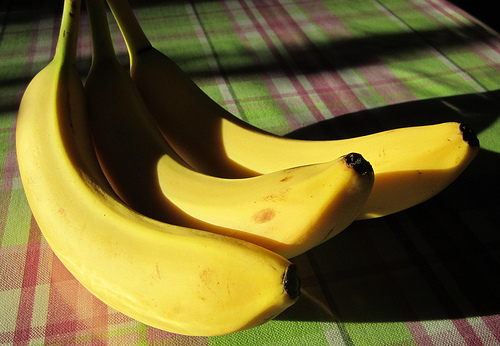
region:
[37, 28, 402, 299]
yellow bananas on table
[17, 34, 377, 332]
bananas are bunched together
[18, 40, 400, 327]
bananas are curved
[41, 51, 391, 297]
bananas are yellow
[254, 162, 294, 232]
small bruises on middle banana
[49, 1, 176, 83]
green spots on stems of bananas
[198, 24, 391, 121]
table under bananas is checked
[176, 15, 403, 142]
table cover is green, red, and white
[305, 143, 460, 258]
ends of bananas are brown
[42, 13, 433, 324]
three bananas in a bunch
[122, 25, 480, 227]
This is a banana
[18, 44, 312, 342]
This is a banana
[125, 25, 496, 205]
This is a ripe banana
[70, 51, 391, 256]
This is a ripe banana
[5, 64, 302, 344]
This is a ripe banana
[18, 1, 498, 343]
This is a bunch of bananas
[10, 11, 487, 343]
These are ripe bananas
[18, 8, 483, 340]
These are yellow-ripe bananas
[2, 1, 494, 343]
These are ripe bananas on a table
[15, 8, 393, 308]
three bananas on table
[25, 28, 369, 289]
three bananas are yellow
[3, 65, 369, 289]
three bananas are curved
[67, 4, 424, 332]
three bananas are connected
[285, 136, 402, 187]
dark point on center banana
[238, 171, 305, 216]
small bruises on center banana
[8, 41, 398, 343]
bananas on red and green table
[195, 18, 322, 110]
table has many stripes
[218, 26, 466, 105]
stripes are red green and white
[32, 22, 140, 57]
green stem on bananas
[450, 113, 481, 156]
The tip of a banana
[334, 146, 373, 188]
the tip of a bannana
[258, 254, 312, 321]
the tip of a banana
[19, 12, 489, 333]
Three bananas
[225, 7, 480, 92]
a green and purple table cloth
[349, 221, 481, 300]
a shadow from the banana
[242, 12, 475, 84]
a shadow from a mysterious object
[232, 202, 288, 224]
some banana bruising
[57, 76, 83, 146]
a scratch on a banana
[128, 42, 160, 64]
a broken tip of a banana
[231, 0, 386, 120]
red stripes on table cloth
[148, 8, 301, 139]
green stripes on tablecloth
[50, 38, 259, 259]
shadow on a banana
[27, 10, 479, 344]
bunch of bananas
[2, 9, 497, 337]
three bananas on a tablecloth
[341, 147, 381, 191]
black tip of banana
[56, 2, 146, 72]
green stems of bananas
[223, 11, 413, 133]
green and red plaid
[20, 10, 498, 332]
three ripe bananas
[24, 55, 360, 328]
ripe yellow banana on a table